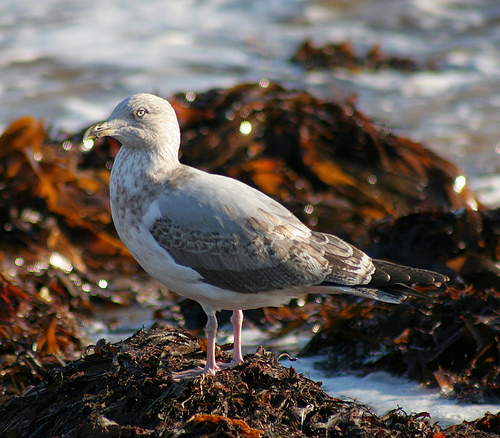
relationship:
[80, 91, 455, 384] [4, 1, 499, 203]
bird by a river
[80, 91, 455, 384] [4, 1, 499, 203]
bird by river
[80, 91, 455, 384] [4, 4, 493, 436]
bird in photo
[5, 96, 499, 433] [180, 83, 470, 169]
ground has leaves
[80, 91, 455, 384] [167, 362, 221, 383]
bird has feet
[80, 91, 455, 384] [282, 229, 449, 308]
bird has a bird's tail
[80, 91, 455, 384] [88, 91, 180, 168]
bird has a head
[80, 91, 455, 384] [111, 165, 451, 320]
bird has feathers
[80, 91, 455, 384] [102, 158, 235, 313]
bird has white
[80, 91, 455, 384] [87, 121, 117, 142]
bird has a beak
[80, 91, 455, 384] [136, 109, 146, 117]
bird has an eye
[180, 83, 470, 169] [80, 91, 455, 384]
seaweed by bird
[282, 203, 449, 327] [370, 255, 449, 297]
bird's tail has black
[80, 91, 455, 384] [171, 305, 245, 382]
bird has legs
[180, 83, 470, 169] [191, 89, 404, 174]
seaweed in a pile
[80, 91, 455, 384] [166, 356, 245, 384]
bird has webbed feet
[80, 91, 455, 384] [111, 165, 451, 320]
bird has gray feathers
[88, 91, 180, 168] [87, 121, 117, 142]
bird's head has beak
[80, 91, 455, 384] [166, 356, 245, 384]
bird has feet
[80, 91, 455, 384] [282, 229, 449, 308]
bird has bird's tail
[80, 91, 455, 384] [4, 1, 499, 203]
seagull in front of seawater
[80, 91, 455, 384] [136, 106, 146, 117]
seagull does not eye